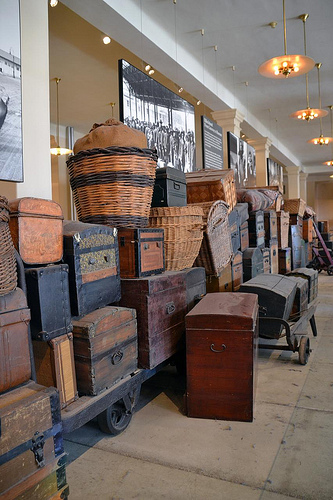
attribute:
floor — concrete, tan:
[95, 430, 332, 485]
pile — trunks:
[14, 151, 313, 459]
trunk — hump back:
[64, 212, 122, 309]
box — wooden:
[183, 292, 262, 422]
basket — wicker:
[195, 195, 237, 282]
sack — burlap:
[71, 116, 152, 149]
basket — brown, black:
[66, 141, 158, 228]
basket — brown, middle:
[73, 178, 153, 216]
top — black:
[64, 144, 160, 163]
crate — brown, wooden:
[176, 289, 264, 421]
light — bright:
[290, 105, 322, 121]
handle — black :
[109, 345, 130, 364]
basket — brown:
[156, 203, 223, 268]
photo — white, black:
[116, 56, 205, 179]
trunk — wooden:
[68, 304, 137, 397]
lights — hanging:
[265, 33, 332, 190]